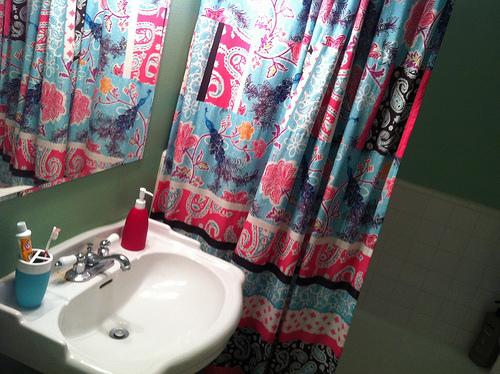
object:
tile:
[416, 220, 441, 247]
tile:
[427, 246, 462, 276]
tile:
[389, 280, 420, 309]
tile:
[396, 258, 428, 290]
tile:
[428, 317, 457, 345]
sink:
[58, 251, 222, 374]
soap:
[121, 187, 154, 251]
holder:
[14, 249, 52, 309]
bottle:
[121, 188, 154, 251]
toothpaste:
[15, 221, 34, 262]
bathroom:
[0, 3, 497, 372]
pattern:
[170, 114, 286, 195]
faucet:
[57, 240, 132, 283]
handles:
[55, 253, 86, 273]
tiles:
[391, 189, 430, 218]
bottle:
[467, 300, 500, 369]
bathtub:
[324, 306, 485, 374]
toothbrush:
[43, 226, 61, 263]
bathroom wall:
[364, 3, 499, 342]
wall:
[2, 0, 202, 270]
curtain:
[148, 0, 449, 374]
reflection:
[1, 0, 169, 181]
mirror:
[0, 1, 169, 197]